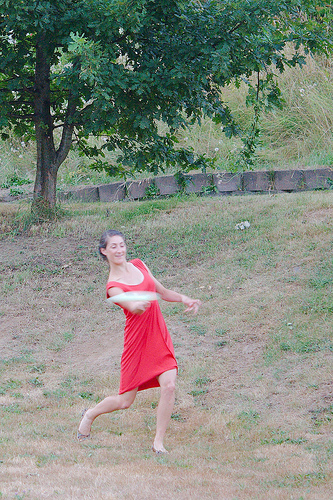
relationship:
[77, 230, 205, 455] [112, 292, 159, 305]
woman throwing a frisbee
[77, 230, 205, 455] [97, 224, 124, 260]
woman has hair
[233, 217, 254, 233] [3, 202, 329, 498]
leaf lying on ground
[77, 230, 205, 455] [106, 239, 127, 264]
woman has a face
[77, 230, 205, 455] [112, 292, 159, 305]
woman catching a frisbee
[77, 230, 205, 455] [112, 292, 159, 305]
woman playing frisbee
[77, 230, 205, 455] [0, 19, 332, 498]
woman in park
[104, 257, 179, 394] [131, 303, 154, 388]
dress has a line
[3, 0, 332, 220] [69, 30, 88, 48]
tree has a leaf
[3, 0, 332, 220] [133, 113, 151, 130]
tree has a leaf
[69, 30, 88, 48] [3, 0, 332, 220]
leaf growing on a tree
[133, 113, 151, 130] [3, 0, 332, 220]
leaf growing on a tree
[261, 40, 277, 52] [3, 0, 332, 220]
leaf on a tree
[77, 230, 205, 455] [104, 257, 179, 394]
woman wearing a dress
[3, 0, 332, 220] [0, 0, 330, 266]
tree in background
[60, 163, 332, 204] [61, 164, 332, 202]
stones are in a formation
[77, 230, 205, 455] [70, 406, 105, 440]
woman has foot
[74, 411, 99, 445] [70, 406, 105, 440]
shoe on foot